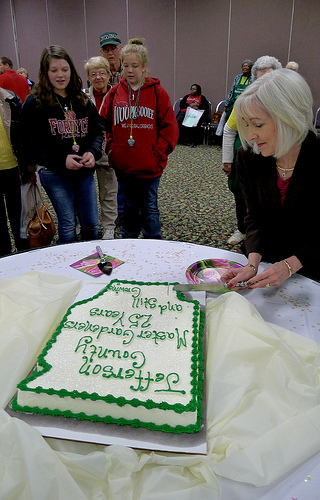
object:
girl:
[97, 38, 177, 241]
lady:
[174, 84, 211, 149]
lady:
[217, 68, 319, 291]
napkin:
[69, 243, 126, 278]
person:
[24, 43, 103, 244]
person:
[82, 55, 118, 238]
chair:
[215, 96, 230, 122]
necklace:
[128, 79, 146, 147]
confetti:
[124, 247, 172, 276]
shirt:
[98, 77, 178, 179]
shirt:
[10, 88, 104, 171]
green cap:
[95, 31, 121, 47]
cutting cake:
[12, 68, 319, 435]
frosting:
[26, 278, 192, 404]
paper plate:
[184, 257, 251, 292]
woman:
[223, 53, 264, 117]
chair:
[199, 100, 210, 126]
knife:
[169, 279, 230, 297]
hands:
[246, 255, 303, 289]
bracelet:
[281, 259, 291, 276]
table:
[0, 238, 319, 500]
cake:
[12, 278, 206, 435]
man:
[97, 27, 124, 85]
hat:
[99, 29, 122, 45]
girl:
[19, 43, 106, 244]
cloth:
[15, 282, 52, 318]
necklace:
[275, 163, 294, 180]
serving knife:
[92, 243, 116, 278]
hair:
[33, 43, 84, 105]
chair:
[169, 97, 213, 143]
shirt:
[223, 69, 252, 116]